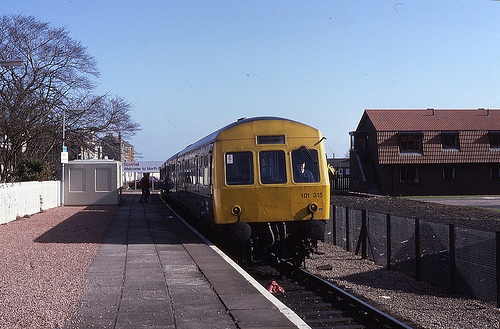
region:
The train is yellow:
[159, 114, 339, 272]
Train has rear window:
[221, 145, 258, 195]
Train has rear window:
[256, 145, 292, 198]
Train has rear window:
[287, 144, 333, 191]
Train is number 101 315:
[296, 190, 330, 202]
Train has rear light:
[224, 203, 254, 218]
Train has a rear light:
[307, 199, 323, 211]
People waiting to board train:
[124, 161, 174, 212]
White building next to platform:
[61, 151, 137, 223]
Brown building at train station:
[352, 92, 493, 204]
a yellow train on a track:
[93, 75, 492, 324]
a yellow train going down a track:
[110, 64, 410, 327]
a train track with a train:
[122, 112, 355, 326]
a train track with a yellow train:
[157, 125, 382, 327]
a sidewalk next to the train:
[82, 115, 310, 327]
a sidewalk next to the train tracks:
[107, 154, 269, 325]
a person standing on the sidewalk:
[129, 157, 167, 209]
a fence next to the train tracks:
[334, 167, 497, 311]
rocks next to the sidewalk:
[21, 204, 126, 326]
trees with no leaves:
[14, 32, 146, 229]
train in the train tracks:
[124, 110, 382, 315]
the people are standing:
[130, 152, 177, 222]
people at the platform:
[120, 147, 180, 232]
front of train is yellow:
[194, 92, 337, 246]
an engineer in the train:
[273, 136, 328, 203]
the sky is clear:
[118, 50, 400, 90]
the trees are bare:
[9, 20, 198, 221]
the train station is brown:
[335, 95, 499, 186]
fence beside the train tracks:
[345, 202, 488, 308]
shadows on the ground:
[36, 186, 228, 276]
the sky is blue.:
[3, 1, 498, 153]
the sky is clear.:
[4, 2, 486, 150]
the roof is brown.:
[353, 100, 497, 136]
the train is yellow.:
[155, 107, 342, 242]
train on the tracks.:
[150, 105, 382, 318]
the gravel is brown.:
[3, 176, 129, 327]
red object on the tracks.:
[260, 273, 288, 295]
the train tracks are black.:
[227, 234, 417, 327]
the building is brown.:
[350, 97, 499, 182]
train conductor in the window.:
[287, 155, 317, 183]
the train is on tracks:
[205, 89, 387, 306]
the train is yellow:
[198, 107, 333, 236]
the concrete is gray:
[107, 230, 174, 323]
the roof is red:
[378, 105, 461, 137]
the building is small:
[57, 157, 124, 205]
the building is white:
[54, 158, 129, 207]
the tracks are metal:
[310, 267, 375, 325]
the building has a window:
[388, 124, 426, 169]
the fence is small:
[395, 222, 465, 284]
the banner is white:
[123, 155, 159, 175]